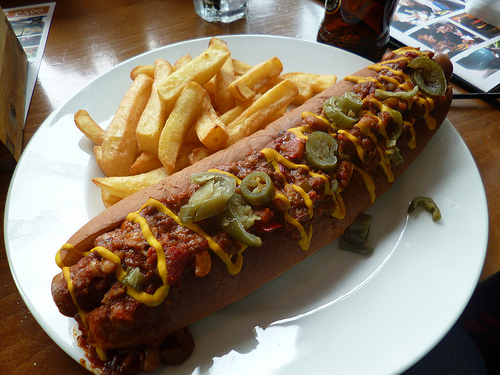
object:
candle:
[193, 0, 251, 24]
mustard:
[127, 213, 177, 295]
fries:
[66, 39, 343, 207]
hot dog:
[44, 33, 460, 373]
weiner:
[46, 42, 455, 375]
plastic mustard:
[87, 246, 154, 308]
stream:
[64, 242, 156, 303]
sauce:
[81, 227, 176, 325]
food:
[49, 35, 455, 373]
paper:
[0, 1, 60, 133]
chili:
[77, 242, 187, 309]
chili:
[193, 155, 334, 235]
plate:
[13, 23, 494, 373]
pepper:
[239, 167, 277, 197]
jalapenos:
[303, 129, 341, 174]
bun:
[0, 32, 490, 375]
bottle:
[306, 0, 412, 65]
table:
[8, 2, 499, 374]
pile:
[75, 36, 336, 178]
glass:
[187, 1, 249, 22]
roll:
[44, 46, 460, 369]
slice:
[405, 190, 443, 230]